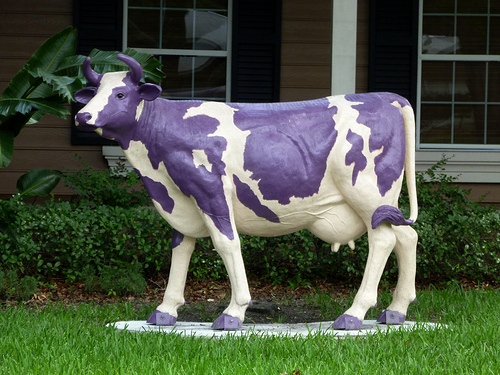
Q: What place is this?
A: It is a garden.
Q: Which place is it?
A: It is a garden.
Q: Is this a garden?
A: Yes, it is a garden.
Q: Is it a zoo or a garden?
A: It is a garden.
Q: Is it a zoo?
A: No, it is a garden.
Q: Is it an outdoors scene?
A: Yes, it is outdoors.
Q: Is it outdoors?
A: Yes, it is outdoors.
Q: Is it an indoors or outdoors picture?
A: It is outdoors.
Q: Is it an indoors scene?
A: No, it is outdoors.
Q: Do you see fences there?
A: No, there are no fences.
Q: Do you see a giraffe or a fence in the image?
A: No, there are no fences or giraffes.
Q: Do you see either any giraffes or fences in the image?
A: No, there are no fences or giraffes.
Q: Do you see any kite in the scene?
A: No, there are no kites.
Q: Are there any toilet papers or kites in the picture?
A: No, there are no kites or toilet papers.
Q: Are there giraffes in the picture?
A: No, there are no giraffes.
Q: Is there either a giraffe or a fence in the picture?
A: No, there are no giraffes or fences.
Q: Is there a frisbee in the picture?
A: No, there are no frisbees.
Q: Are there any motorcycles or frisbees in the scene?
A: No, there are no frisbees or motorcycles.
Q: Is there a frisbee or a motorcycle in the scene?
A: No, there are no frisbees or motorcycles.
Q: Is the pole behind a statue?
A: Yes, the pole is behind a statue.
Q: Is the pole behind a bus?
A: No, the pole is behind a statue.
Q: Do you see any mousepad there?
A: No, there are no mouse pads.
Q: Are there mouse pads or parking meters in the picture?
A: No, there are no mouse pads or parking meters.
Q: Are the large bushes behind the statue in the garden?
A: Yes, the bushes are behind the statue.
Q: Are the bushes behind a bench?
A: No, the bushes are behind the statue.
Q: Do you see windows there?
A: Yes, there is a window.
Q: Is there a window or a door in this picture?
A: Yes, there is a window.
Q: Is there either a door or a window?
A: Yes, there is a window.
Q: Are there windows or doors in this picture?
A: Yes, there is a window.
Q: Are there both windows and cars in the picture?
A: No, there is a window but no cars.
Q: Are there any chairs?
A: No, there are no chairs.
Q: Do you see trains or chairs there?
A: No, there are no chairs or trains.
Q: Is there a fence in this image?
A: No, there are no fences.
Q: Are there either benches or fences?
A: No, there are no fences or benches.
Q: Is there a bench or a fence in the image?
A: No, there are no fences or benches.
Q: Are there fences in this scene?
A: No, there are no fences.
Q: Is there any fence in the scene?
A: No, there are no fences.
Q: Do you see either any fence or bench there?
A: No, there are no fences or benches.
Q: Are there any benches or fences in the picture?
A: No, there are no fences or benches.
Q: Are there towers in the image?
A: No, there are no towers.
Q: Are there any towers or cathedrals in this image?
A: No, there are no towers or cathedrals.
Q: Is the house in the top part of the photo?
A: Yes, the house is in the top of the image.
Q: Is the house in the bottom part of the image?
A: No, the house is in the top of the image.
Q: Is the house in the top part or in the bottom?
A: The house is in the top of the image.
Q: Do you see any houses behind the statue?
A: Yes, there is a house behind the statue.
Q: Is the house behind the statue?
A: Yes, the house is behind the statue.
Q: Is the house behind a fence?
A: No, the house is behind the statue.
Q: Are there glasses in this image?
A: No, there are no glasses.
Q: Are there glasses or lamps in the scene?
A: No, there are no glasses or lamps.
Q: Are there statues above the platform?
A: Yes, there is a statue above the platform.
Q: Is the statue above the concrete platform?
A: Yes, the statue is above the platform.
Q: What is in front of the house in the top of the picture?
A: The statue is in front of the house.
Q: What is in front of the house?
A: The statue is in front of the house.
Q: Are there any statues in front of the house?
A: Yes, there is a statue in front of the house.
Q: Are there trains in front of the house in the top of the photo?
A: No, there is a statue in front of the house.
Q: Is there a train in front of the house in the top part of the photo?
A: No, there is a statue in front of the house.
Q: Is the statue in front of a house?
A: Yes, the statue is in front of a house.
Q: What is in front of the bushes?
A: The statue is in front of the bushes.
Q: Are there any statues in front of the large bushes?
A: Yes, there is a statue in front of the bushes.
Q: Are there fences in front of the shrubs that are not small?
A: No, there is a statue in front of the bushes.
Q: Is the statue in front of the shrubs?
A: Yes, the statue is in front of the shrubs.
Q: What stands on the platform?
A: The statue stands on the platform.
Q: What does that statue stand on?
A: The statue stands on the platform.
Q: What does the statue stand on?
A: The statue stands on the platform.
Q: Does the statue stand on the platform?
A: Yes, the statue stands on the platform.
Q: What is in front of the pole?
A: The statue is in front of the pole.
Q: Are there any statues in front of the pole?
A: Yes, there is a statue in front of the pole.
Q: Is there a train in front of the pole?
A: No, there is a statue in front of the pole.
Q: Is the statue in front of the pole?
A: Yes, the statue is in front of the pole.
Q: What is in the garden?
A: The statue is in the garden.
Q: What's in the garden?
A: The statue is in the garden.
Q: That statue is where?
A: The statue is in the garden.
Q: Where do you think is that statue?
A: The statue is in the garden.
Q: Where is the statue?
A: The statue is in the garden.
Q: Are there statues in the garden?
A: Yes, there is a statue in the garden.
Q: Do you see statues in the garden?
A: Yes, there is a statue in the garden.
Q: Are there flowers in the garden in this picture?
A: No, there is a statue in the garden.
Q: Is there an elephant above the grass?
A: No, there is a statue above the grass.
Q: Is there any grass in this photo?
A: Yes, there is grass.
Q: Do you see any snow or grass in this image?
A: Yes, there is grass.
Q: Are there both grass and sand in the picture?
A: No, there is grass but no sand.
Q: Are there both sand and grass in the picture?
A: No, there is grass but no sand.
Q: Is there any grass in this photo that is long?
A: Yes, there is long grass.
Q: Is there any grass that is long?
A: Yes, there is grass that is long.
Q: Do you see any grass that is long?
A: Yes, there is grass that is long.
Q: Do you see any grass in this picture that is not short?
A: Yes, there is long grass.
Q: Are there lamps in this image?
A: No, there are no lamps.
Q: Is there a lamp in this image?
A: No, there are no lamps.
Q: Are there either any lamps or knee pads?
A: No, there are no lamps or knee pads.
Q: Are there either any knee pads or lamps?
A: No, there are no lamps or knee pads.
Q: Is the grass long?
A: Yes, the grass is long.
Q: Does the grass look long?
A: Yes, the grass is long.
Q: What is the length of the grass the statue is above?
A: The grass is long.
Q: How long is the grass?
A: The grass is long.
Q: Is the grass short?
A: No, the grass is long.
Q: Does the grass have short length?
A: No, the grass is long.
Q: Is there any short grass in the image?
A: No, there is grass but it is long.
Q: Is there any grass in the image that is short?
A: No, there is grass but it is long.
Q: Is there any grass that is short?
A: No, there is grass but it is long.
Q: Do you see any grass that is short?
A: No, there is grass but it is long.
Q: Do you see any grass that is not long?
A: No, there is grass but it is long.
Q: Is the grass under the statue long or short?
A: The grass is long.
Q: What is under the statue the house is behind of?
A: The grass is under the statue.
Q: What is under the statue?
A: The grass is under the statue.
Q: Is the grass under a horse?
A: No, the grass is under the statue.